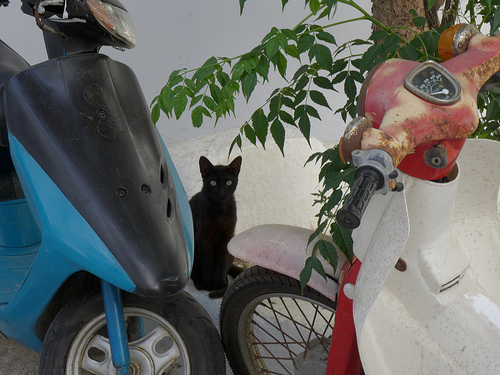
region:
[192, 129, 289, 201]
the head of a cat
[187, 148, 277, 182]
the ear of a cat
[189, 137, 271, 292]
the body of a cat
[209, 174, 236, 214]
the mouth of a cat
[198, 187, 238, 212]
the nose of a cat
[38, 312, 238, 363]
the wheel on a bike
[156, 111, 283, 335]
a all black cat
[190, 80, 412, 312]
a cat near a bike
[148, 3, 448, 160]
green leaves on branches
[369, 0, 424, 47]
bark on tree trunk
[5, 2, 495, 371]
front of two parked scooters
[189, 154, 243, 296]
black cat sitting on ground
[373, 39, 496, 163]
rusted metal on scooter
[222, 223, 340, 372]
white fender over tire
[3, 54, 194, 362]
black and blue of scooter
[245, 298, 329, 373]
spokes in scooter tire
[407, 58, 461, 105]
gauge on top of scooter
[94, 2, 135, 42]
light on front of scooter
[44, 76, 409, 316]
a cat between two mopeds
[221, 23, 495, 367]
a rusty red and white moped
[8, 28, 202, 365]
a blue and black moped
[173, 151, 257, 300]
a black cat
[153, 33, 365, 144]
the green foliage of a small tree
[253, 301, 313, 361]
the spokes on a moped wheel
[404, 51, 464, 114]
the speedometer on a moped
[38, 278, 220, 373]
the front wheel of a moped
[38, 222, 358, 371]
the front wheels of two mopeds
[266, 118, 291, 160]
a leaf on a small tree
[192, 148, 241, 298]
one sitting black cat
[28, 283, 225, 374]
one round black scooter wheel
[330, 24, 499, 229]
rusted red scooter handlebars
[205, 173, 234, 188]
two light colored cat eyes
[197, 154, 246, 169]
two black pointed cat ears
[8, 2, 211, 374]
front of blue and black scooter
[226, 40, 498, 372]
rusted white and red scooter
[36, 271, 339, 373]
two round black scooter tires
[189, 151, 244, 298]
cat next to motorbikes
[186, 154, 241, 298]
a small black cat on the ground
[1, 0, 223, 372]
motorbike on the left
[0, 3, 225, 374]
black and blue motorbike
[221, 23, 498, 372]
motorbike on the right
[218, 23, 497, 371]
red and white motorbike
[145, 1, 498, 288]
green leaves hanging from tree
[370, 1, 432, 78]
part of tree trunk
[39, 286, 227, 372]
wheel of black and blue motorbike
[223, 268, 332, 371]
wheel of red and white motorbike